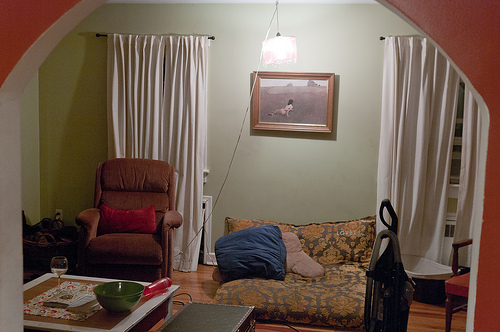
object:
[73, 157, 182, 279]
recliner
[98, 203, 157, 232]
pillow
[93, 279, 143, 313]
bowl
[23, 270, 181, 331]
table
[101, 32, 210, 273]
curtains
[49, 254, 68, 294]
wine glass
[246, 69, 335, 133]
painting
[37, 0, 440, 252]
wall